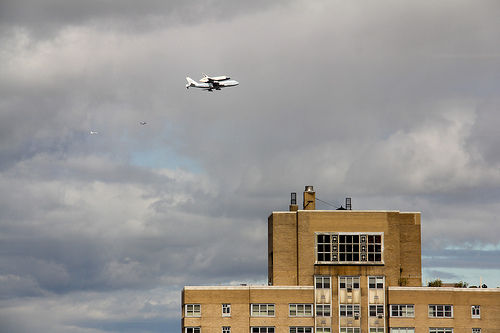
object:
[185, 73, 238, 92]
plane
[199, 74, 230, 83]
shuttle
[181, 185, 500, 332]
building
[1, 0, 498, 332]
sky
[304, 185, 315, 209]
chimney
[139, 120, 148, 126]
jet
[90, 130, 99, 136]
jet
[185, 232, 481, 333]
windows